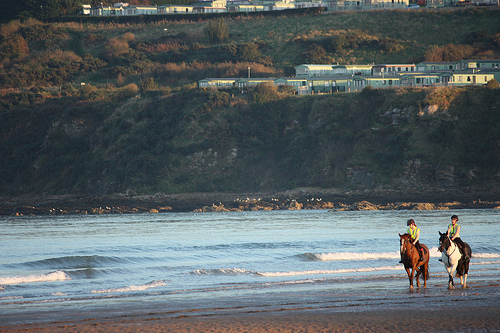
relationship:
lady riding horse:
[398, 219, 423, 264] [398, 233, 429, 293]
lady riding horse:
[445, 214, 466, 262] [398, 233, 430, 293]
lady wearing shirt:
[398, 219, 423, 264] [407, 225, 420, 239]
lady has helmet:
[398, 219, 423, 264] [408, 219, 416, 227]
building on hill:
[351, 72, 401, 90] [1, 89, 498, 210]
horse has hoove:
[398, 233, 429, 293] [409, 285, 415, 291]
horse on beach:
[398, 233, 429, 293] [0, 299, 498, 332]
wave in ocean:
[7, 253, 197, 269] [0, 207, 499, 315]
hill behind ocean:
[1, 89, 498, 210] [0, 207, 499, 315]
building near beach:
[351, 72, 401, 90] [0, 299, 498, 332]